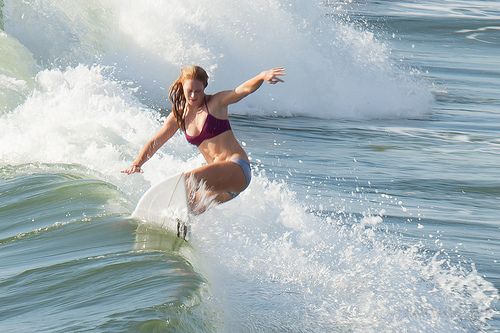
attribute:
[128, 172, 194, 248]
board — white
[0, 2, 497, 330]
ocean — blue, green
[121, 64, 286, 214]
woman — shoulder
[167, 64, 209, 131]
hair — long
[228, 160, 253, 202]
bottoms — blue, bikini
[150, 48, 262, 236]
surfer — riding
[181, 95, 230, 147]
bikini top — red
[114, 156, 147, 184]
woman's hand — womans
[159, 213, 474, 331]
waves — white, water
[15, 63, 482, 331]
wave — white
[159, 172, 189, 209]
tip — white